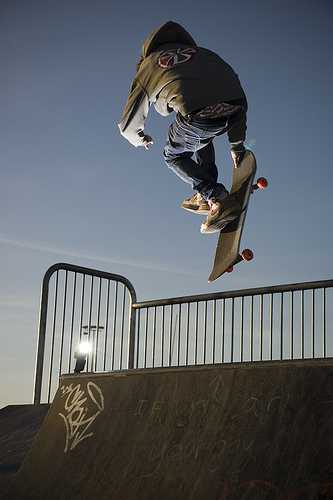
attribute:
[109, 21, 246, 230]
man — jumping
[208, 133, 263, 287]
skateboard — black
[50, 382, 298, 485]
graffiti — white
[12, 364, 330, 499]
ramp — cement, brown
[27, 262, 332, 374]
fence — metal, grey, silver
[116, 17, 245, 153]
hoodie — khaki, grey, green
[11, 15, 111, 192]
sky — blue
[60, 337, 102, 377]
light — lit, shining, glowing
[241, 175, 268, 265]
wheels — orange, small, red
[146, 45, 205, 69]
graphic — red, white, black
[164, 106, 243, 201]
jeans — blue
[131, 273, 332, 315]
pole — metal